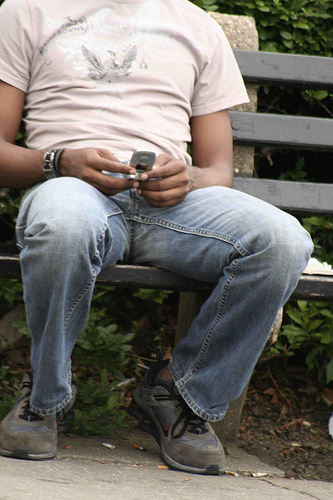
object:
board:
[113, 265, 161, 290]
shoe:
[126, 357, 227, 475]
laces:
[18, 380, 67, 423]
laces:
[153, 392, 209, 440]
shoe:
[0, 369, 77, 460]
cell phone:
[125, 151, 156, 181]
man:
[0, 0, 314, 477]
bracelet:
[42, 147, 66, 180]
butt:
[158, 464, 170, 469]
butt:
[62, 445, 72, 450]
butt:
[101, 443, 116, 450]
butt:
[101, 442, 116, 449]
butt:
[251, 473, 268, 478]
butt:
[226, 470, 239, 476]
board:
[293, 272, 333, 301]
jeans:
[15, 158, 314, 424]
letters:
[37, 14, 89, 67]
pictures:
[80, 43, 148, 84]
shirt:
[0, 0, 251, 174]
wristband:
[33, 147, 70, 182]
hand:
[41, 146, 140, 196]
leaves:
[293, 29, 317, 38]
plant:
[277, 0, 331, 44]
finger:
[93, 155, 137, 175]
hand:
[137, 153, 193, 207]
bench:
[231, 48, 333, 86]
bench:
[227, 109, 332, 152]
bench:
[233, 174, 333, 212]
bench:
[0, 255, 333, 301]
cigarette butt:
[133, 444, 147, 451]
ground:
[0, 404, 333, 500]